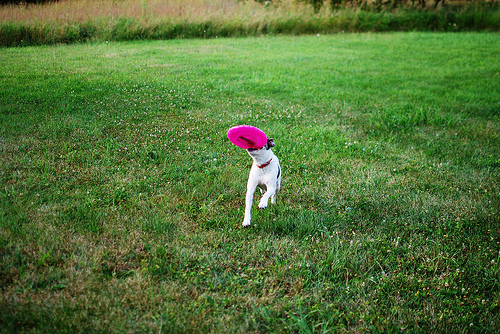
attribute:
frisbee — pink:
[228, 122, 268, 153]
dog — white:
[241, 139, 281, 226]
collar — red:
[251, 155, 273, 171]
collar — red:
[256, 157, 272, 171]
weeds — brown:
[15, 9, 88, 19]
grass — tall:
[3, 4, 373, 44]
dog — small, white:
[223, 122, 285, 229]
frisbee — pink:
[221, 122, 268, 150]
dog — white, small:
[231, 143, 284, 228]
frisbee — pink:
[228, 121, 268, 148]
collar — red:
[245, 157, 287, 175]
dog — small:
[216, 120, 292, 246]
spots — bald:
[101, 43, 217, 68]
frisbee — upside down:
[225, 125, 267, 148]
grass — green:
[1, 25, 497, 330]